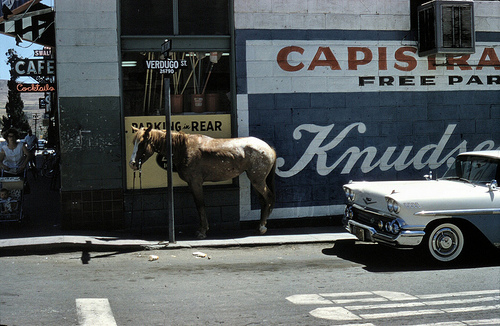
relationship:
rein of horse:
[127, 153, 146, 182] [118, 99, 301, 231]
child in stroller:
[2, 190, 20, 230] [0, 166, 27, 234]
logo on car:
[351, 174, 382, 213] [344, 139, 497, 265]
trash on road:
[113, 247, 205, 271] [144, 277, 219, 323]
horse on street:
[118, 99, 301, 231] [99, 265, 301, 317]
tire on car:
[406, 229, 458, 265] [344, 139, 497, 265]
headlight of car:
[378, 190, 408, 224] [344, 139, 497, 265]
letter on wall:
[259, 111, 492, 183] [251, 8, 484, 219]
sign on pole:
[142, 55, 191, 72] [154, 84, 193, 246]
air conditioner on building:
[412, 8, 486, 65] [5, 7, 484, 213]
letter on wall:
[259, 111, 492, 183] [279, 33, 476, 84]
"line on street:
[64, 284, 115, 324] [99, 265, 301, 317]